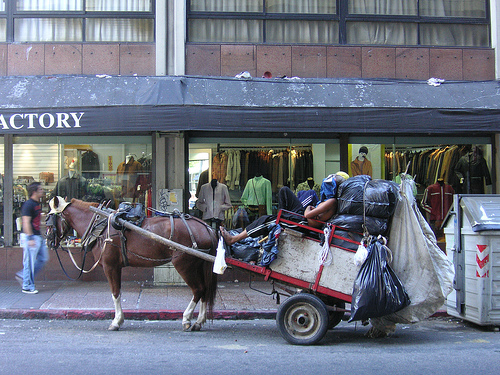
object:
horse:
[39, 195, 217, 332]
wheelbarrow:
[217, 208, 393, 345]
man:
[220, 174, 348, 246]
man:
[15, 182, 50, 294]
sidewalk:
[2, 277, 272, 323]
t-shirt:
[20, 198, 42, 235]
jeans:
[16, 233, 51, 291]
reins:
[52, 228, 113, 280]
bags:
[348, 239, 412, 324]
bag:
[368, 195, 454, 335]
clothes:
[196, 181, 232, 221]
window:
[185, 132, 348, 223]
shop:
[0, 129, 499, 253]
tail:
[203, 262, 218, 329]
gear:
[43, 195, 117, 253]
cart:
[88, 205, 393, 345]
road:
[4, 315, 499, 374]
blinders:
[44, 213, 58, 233]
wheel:
[276, 293, 330, 345]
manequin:
[195, 179, 232, 223]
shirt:
[240, 176, 273, 215]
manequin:
[240, 175, 273, 215]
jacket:
[420, 182, 455, 224]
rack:
[212, 142, 326, 185]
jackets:
[212, 148, 242, 191]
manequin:
[421, 179, 456, 221]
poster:
[348, 144, 386, 180]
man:
[351, 146, 372, 180]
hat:
[359, 146, 369, 155]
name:
[0, 111, 85, 130]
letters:
[56, 111, 85, 128]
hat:
[47, 196, 71, 215]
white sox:
[108, 293, 124, 330]